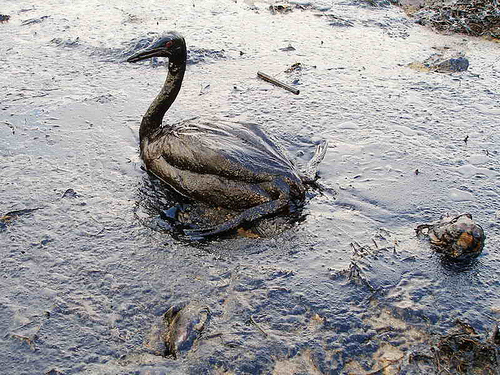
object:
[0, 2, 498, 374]
debris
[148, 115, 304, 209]
body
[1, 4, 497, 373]
muck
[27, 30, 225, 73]
ripples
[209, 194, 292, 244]
leg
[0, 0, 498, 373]
mud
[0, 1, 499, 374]
water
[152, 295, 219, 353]
rock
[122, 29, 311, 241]
duck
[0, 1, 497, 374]
oil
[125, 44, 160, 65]
beak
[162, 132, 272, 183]
wing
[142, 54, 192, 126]
neck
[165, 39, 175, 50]
eye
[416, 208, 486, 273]
rock